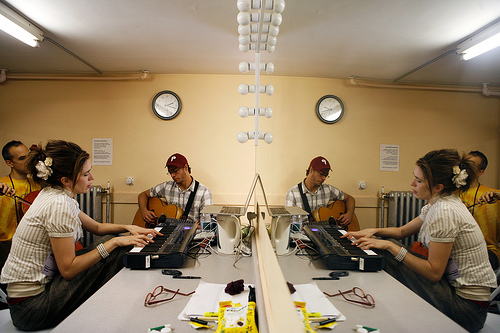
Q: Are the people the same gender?
A: No, they are both male and female.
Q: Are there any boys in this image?
A: No, there are no boys.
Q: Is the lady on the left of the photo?
A: Yes, the lady is on the left of the image.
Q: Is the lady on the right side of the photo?
A: No, the lady is on the left of the image.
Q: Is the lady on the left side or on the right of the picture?
A: The lady is on the left of the image.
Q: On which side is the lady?
A: The lady is on the left of the image.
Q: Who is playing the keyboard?
A: The lady is playing the keyboard.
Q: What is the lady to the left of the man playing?
A: The lady is playing the keyboard.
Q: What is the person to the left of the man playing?
A: The lady is playing the keyboard.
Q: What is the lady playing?
A: The lady is playing the keyboard.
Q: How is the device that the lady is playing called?
A: The device is a keyboard.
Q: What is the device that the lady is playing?
A: The device is a keyboard.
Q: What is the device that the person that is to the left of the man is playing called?
A: The device is a keyboard.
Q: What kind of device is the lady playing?
A: The lady is playing the keyboard.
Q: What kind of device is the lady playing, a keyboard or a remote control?
A: The lady is playing a keyboard.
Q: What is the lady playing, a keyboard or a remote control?
A: The lady is playing a keyboard.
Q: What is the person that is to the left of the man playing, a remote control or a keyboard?
A: The lady is playing a keyboard.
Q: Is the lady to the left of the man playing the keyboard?
A: Yes, the lady is playing the keyboard.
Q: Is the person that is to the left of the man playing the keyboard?
A: Yes, the lady is playing the keyboard.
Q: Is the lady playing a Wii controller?
A: No, the lady is playing the keyboard.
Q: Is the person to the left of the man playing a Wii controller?
A: No, the lady is playing the keyboard.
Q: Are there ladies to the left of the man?
A: Yes, there is a lady to the left of the man.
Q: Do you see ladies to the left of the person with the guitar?
A: Yes, there is a lady to the left of the man.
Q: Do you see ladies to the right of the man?
A: No, the lady is to the left of the man.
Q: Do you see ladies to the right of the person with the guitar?
A: No, the lady is to the left of the man.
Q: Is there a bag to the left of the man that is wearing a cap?
A: No, there is a lady to the left of the man.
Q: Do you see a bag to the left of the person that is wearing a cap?
A: No, there is a lady to the left of the man.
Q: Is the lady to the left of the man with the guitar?
A: Yes, the lady is to the left of the man.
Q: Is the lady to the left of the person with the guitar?
A: Yes, the lady is to the left of the man.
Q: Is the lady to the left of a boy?
A: No, the lady is to the left of the man.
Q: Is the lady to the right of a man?
A: No, the lady is to the left of a man.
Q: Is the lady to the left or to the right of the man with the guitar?
A: The lady is to the left of the man.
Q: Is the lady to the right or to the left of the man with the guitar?
A: The lady is to the left of the man.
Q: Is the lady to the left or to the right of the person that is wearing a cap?
A: The lady is to the left of the man.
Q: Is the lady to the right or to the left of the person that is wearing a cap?
A: The lady is to the left of the man.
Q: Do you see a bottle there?
A: No, there are no bottles.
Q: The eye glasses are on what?
A: The eye glasses are on the counter.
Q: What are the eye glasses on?
A: The eye glasses are on the counter.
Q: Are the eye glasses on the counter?
A: Yes, the eye glasses are on the counter.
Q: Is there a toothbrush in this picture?
A: No, there are no toothbrushes.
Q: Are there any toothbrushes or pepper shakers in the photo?
A: No, there are no toothbrushes or pepper shakers.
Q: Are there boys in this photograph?
A: No, there are no boys.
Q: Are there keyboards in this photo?
A: Yes, there is a keyboard.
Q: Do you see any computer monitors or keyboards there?
A: Yes, there is a keyboard.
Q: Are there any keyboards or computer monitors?
A: Yes, there is a keyboard.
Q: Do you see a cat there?
A: No, there are no cats.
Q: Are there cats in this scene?
A: No, there are no cats.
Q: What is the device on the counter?
A: The device is a keyboard.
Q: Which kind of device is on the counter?
A: The device is a keyboard.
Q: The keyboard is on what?
A: The keyboard is on the counter.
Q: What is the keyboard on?
A: The keyboard is on the counter.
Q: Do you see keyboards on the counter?
A: Yes, there is a keyboard on the counter.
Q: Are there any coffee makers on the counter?
A: No, there is a keyboard on the counter.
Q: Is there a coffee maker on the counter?
A: No, there is a keyboard on the counter.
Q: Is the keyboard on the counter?
A: Yes, the keyboard is on the counter.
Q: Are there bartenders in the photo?
A: No, there are no bartenders.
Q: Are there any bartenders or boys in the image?
A: No, there are no bartenders or boys.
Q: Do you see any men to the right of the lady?
A: Yes, there is a man to the right of the lady.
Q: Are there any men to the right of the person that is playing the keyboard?
A: Yes, there is a man to the right of the lady.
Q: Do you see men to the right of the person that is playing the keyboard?
A: Yes, there is a man to the right of the lady.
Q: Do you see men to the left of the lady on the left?
A: No, the man is to the right of the lady.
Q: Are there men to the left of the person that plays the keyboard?
A: No, the man is to the right of the lady.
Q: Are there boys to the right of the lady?
A: No, there is a man to the right of the lady.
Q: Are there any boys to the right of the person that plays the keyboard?
A: No, there is a man to the right of the lady.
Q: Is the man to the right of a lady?
A: Yes, the man is to the right of a lady.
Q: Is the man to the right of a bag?
A: No, the man is to the right of a lady.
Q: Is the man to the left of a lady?
A: No, the man is to the right of a lady.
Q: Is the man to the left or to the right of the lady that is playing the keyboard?
A: The man is to the right of the lady.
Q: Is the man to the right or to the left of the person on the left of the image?
A: The man is to the right of the lady.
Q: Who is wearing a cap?
A: The man is wearing a cap.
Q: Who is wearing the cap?
A: The man is wearing a cap.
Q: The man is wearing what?
A: The man is wearing a cap.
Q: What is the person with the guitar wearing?
A: The man is wearing a cap.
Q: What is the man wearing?
A: The man is wearing a cap.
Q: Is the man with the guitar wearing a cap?
A: Yes, the man is wearing a cap.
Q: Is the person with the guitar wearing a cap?
A: Yes, the man is wearing a cap.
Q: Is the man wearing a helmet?
A: No, the man is wearing a cap.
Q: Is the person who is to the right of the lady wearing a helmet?
A: No, the man is wearing a cap.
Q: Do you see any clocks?
A: Yes, there is a clock.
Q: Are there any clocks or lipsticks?
A: Yes, there is a clock.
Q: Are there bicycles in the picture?
A: No, there are no bicycles.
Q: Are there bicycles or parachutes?
A: No, there are no bicycles or parachutes.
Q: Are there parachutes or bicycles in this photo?
A: No, there are no bicycles or parachutes.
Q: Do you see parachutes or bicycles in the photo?
A: No, there are no bicycles or parachutes.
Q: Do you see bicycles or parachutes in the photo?
A: No, there are no bicycles or parachutes.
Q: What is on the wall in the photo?
A: The clock is on the wall.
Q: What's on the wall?
A: The clock is on the wall.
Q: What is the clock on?
A: The clock is on the wall.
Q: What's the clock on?
A: The clock is on the wall.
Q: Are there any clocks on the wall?
A: Yes, there is a clock on the wall.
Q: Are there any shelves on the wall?
A: No, there is a clock on the wall.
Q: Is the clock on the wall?
A: Yes, the clock is on the wall.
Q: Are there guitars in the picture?
A: Yes, there is a guitar.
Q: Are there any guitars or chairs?
A: Yes, there is a guitar.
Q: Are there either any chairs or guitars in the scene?
A: Yes, there is a guitar.